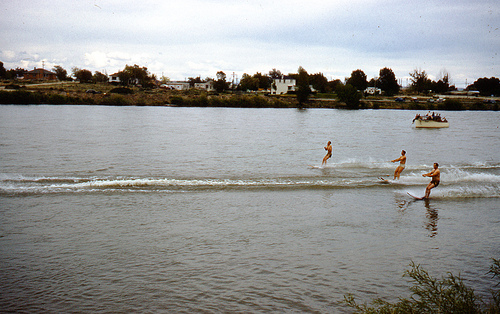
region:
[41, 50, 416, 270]
this is a river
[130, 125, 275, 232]
the water has waves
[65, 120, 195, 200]
the water is green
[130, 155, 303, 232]
the waves are white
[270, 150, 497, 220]
these are surfers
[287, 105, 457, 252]
the people are jet skiing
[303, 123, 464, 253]
there are three people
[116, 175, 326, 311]
the waters are calm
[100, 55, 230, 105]
this is a town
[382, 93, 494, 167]
this is a boat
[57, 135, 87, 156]
white and blue ocean waves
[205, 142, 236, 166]
white and blue ocean waveswhite and blue ocean waves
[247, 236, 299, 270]
white and blue ocean waves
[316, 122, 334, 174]
woman doing tricks in water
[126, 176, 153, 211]
white and blue ocean waves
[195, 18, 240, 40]
white clouds in blue sky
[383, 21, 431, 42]
white clouds in blue sky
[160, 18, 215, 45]
white clouds in blue sky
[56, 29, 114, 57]
white clouds in blue sky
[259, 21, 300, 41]
white clouds in blue sky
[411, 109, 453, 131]
People inside of a boat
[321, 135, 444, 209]
three people water skiing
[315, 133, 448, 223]
three people water skiing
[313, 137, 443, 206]
three people water skiing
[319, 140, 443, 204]
three people water skiing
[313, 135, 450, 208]
three people water skiing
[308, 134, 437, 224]
three people water skiing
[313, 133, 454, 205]
three people water skiing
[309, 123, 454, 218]
three people water skiing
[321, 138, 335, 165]
The person on the left water skiing.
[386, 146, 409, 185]
The person in the middle water skiing.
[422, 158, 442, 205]
The person on the right water skiiing.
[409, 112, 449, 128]
The boat in the water.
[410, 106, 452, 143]
People in a white boat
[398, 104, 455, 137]
White boat in the water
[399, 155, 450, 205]
Man water skiing on the river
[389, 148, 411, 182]
Man water skiing on the river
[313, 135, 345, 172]
Man water skiing on the river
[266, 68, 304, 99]
house on the river bank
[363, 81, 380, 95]
house on the river bank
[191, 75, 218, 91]
house on the river bank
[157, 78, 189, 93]
house on the river bank